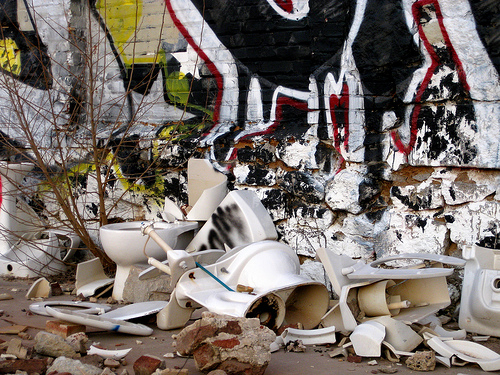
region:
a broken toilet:
[188, 184, 317, 332]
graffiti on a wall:
[179, 5, 472, 162]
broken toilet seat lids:
[28, 294, 163, 349]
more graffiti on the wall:
[12, 16, 167, 116]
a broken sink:
[455, 250, 495, 345]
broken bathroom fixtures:
[132, 215, 219, 339]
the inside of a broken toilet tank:
[348, 281, 476, 356]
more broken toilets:
[90, 197, 216, 310]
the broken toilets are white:
[11, 158, 196, 371]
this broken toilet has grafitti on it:
[191, 192, 296, 337]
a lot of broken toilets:
[10, 112, 499, 371]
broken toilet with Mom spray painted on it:
[166, 160, 337, 357]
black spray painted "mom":
[179, 165, 279, 263]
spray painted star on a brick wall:
[96, 28, 249, 180]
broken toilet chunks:
[289, 203, 498, 355]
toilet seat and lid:
[10, 263, 207, 343]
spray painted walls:
[110, 3, 499, 211]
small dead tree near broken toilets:
[39, 2, 190, 326]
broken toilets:
[71, 148, 453, 370]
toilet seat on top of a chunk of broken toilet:
[283, 206, 465, 348]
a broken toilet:
[338, 244, 468, 358]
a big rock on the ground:
[156, 298, 288, 373]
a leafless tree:
[16, 121, 208, 268]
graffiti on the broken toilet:
[138, 201, 295, 273]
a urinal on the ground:
[8, 223, 68, 288]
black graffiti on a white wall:
[341, 114, 498, 193]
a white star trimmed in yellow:
[93, 76, 218, 173]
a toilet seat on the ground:
[33, 297, 120, 322]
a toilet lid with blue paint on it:
[48, 305, 165, 350]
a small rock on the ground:
[376, 330, 443, 372]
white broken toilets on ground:
[91, 188, 406, 333]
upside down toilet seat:
[349, 254, 466, 281]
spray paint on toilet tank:
[207, 199, 252, 252]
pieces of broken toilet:
[281, 322, 386, 358]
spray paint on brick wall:
[219, 59, 344, 131]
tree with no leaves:
[34, 79, 123, 191]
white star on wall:
[125, 71, 196, 155]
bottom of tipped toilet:
[249, 281, 333, 336]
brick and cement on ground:
[191, 322, 271, 373]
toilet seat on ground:
[25, 295, 106, 318]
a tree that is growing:
[0, 2, 213, 267]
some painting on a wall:
[0, 3, 499, 270]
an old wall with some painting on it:
[1, 0, 492, 262]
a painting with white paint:
[2, 1, 494, 265]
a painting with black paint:
[1, 0, 496, 277]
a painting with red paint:
[1, 0, 498, 273]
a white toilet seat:
[98, 213, 186, 297]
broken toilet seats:
[8, 155, 498, 354]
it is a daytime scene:
[3, 5, 494, 372]